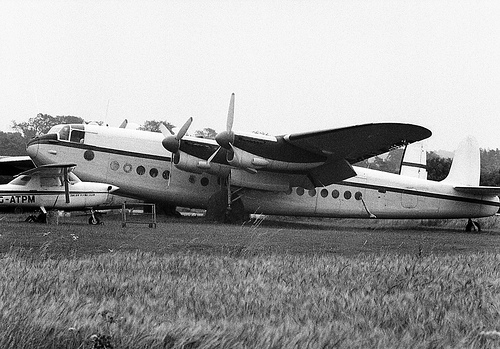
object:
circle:
[136, 165, 146, 176]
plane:
[24, 91, 500, 233]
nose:
[24, 126, 59, 166]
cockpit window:
[59, 124, 85, 143]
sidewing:
[166, 112, 438, 194]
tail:
[396, 135, 500, 219]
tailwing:
[455, 178, 500, 203]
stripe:
[46, 136, 498, 217]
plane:
[0, 164, 145, 227]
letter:
[8, 195, 16, 205]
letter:
[15, 194, 21, 203]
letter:
[20, 194, 28, 204]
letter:
[27, 195, 35, 203]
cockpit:
[29, 123, 85, 145]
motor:
[222, 135, 281, 174]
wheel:
[464, 221, 482, 234]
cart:
[121, 202, 158, 228]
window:
[136, 165, 146, 175]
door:
[399, 192, 418, 208]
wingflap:
[308, 154, 360, 185]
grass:
[231, 206, 283, 266]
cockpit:
[37, 170, 79, 191]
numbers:
[70, 193, 97, 197]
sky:
[0, 0, 499, 149]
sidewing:
[1, 185, 56, 204]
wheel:
[88, 215, 100, 225]